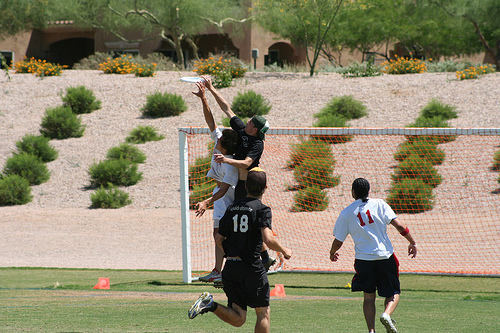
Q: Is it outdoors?
A: Yes, it is outdoors.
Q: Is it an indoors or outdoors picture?
A: It is outdoors.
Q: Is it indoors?
A: No, it is outdoors.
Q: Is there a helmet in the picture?
A: No, there are no helmets.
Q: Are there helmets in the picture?
A: No, there are no helmets.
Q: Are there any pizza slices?
A: No, there are no pizza slices.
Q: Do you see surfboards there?
A: No, there are no surfboards.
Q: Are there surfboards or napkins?
A: No, there are no surfboards or napkins.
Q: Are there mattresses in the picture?
A: No, there are no mattresses.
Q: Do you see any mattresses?
A: No, there are no mattresses.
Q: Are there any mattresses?
A: No, there are no mattresses.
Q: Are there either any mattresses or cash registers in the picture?
A: No, there are no mattresses or cash registers.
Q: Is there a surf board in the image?
A: No, there are no surfboards.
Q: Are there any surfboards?
A: No, there are no surfboards.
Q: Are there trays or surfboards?
A: No, there are no surfboards or trays.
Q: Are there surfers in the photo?
A: No, there are no surfers.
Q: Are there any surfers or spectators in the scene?
A: No, there are no surfers or spectators.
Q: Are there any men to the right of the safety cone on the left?
A: Yes, there is a man to the right of the cone.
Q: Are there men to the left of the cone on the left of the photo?
A: No, the man is to the right of the cone.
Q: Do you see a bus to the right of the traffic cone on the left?
A: No, there is a man to the right of the traffic cone.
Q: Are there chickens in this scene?
A: No, there are no chickens.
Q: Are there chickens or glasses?
A: No, there are no chickens or glasses.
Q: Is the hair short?
A: Yes, the hair is short.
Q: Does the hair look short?
A: Yes, the hair is short.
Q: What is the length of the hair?
A: The hair is short.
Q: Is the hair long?
A: No, the hair is short.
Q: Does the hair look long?
A: No, the hair is short.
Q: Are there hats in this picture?
A: Yes, there is a hat.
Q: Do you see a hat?
A: Yes, there is a hat.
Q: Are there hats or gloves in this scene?
A: Yes, there is a hat.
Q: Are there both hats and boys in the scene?
A: No, there is a hat but no boys.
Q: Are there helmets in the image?
A: No, there are no helmets.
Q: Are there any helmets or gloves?
A: No, there are no helmets or gloves.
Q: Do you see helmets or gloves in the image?
A: No, there are no helmets or gloves.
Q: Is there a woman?
A: No, there are no women.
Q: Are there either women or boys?
A: No, there are no women or boys.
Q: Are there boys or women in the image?
A: No, there are no women or boys.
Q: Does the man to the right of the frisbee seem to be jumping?
A: Yes, the man is jumping.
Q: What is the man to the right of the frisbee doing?
A: The man is jumping.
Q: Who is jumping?
A: The man is jumping.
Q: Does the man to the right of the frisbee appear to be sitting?
A: No, the man is jumping.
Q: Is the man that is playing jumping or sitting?
A: The man is jumping.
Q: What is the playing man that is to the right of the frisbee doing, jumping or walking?
A: The man is jumping.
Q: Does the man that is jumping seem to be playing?
A: Yes, the man is playing.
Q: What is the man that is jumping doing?
A: The man is playing.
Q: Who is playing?
A: The man is playing.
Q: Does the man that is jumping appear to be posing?
A: No, the man is playing.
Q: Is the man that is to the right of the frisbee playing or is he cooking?
A: The man is playing.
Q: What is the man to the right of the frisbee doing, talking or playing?
A: The man is playing.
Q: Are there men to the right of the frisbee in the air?
A: Yes, there is a man to the right of the frisbee.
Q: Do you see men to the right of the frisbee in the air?
A: Yes, there is a man to the right of the frisbee.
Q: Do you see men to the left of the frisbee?
A: No, the man is to the right of the frisbee.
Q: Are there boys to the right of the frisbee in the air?
A: No, there is a man to the right of the frisbee.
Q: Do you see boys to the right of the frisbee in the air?
A: No, there is a man to the right of the frisbee.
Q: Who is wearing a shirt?
A: The man is wearing a shirt.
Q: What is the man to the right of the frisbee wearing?
A: The man is wearing a shirt.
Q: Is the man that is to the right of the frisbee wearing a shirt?
A: Yes, the man is wearing a shirt.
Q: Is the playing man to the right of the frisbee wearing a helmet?
A: No, the man is wearing a shirt.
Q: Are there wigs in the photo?
A: No, there are no wigs.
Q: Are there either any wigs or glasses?
A: No, there are no wigs or glasses.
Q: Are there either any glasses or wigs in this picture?
A: No, there are no wigs or glasses.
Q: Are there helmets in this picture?
A: No, there are no helmets.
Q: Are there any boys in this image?
A: No, there are no boys.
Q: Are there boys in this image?
A: No, there are no boys.